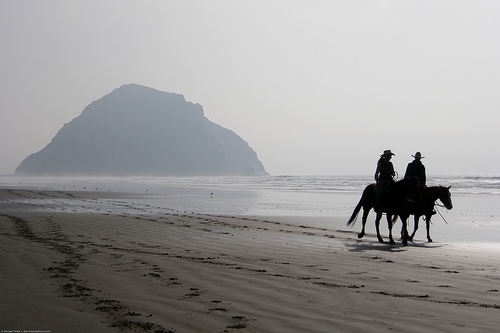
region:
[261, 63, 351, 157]
part of the white sky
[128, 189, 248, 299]
part of the sandy beach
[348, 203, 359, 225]
tail of a horse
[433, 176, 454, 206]
head of a horse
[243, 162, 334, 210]
part of a shore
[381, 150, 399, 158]
part of a dark hat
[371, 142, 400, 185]
a lady on a horse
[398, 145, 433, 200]
a man on a horse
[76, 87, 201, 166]
part of a hill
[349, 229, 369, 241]
hoof of a horse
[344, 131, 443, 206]
two people riding horses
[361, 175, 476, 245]
there are two horses walking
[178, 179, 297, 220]
the sand is wet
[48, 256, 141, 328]
the sand has footprints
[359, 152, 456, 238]
the horses are walking at the beach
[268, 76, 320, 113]
the sky is gray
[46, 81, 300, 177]
the mountain is foggy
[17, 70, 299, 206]
there is a small island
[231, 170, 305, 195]
the water is calm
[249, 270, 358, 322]
the sand is gray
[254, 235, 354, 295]
part of a sandy beach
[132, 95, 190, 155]
part of a hill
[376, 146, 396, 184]
a woman on a horse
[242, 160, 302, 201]
part of the shore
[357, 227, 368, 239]
a hoof a horse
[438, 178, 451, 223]
head of horse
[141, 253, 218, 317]
foot tracks on the sand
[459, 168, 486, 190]
part of a water body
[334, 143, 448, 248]
a couple horseback riding on the beach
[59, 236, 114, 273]
foot prints in the sand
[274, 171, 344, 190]
a gray open sea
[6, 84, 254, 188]
a small mountain near the beach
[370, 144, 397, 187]
a woman wearing a hat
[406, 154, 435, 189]
a man wearing a hat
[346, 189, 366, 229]
a long silky horse tail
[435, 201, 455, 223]
reins hanging on a horse head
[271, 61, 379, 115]
a cloudy white sky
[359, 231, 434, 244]
hooves on horse feet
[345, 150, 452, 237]
this is a man and a woman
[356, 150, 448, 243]
they are riding on horses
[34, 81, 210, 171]
the mountain is tall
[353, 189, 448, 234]
the horses are two in number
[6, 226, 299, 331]
the place is full of sand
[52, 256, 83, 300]
these are footsteps on the sand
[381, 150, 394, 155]
the woman is wearing a hat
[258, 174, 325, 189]
th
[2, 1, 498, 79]
the sky is grey in color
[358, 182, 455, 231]
the horses are black in color